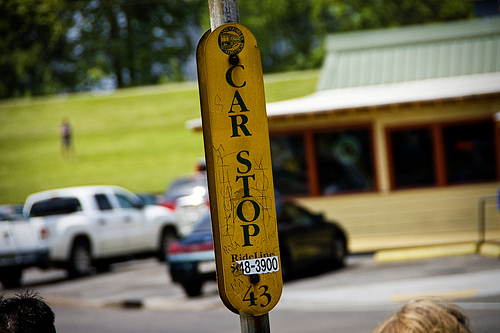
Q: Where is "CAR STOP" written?
A: On yellow sign.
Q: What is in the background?
A: Trees.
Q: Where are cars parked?
A: In a parking lot.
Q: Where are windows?
A: On a building.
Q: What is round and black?
A: Tires.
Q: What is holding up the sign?
A: A post.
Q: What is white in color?
A: Truck.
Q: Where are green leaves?
A: On trees.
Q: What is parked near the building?
A: The white truck.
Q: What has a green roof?
A: The building.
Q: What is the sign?
A: Yellow.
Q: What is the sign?
A: Yellow.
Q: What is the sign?
A: Yellow.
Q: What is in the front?
A: Sign.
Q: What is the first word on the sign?
A: Car.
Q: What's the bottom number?
A: 43.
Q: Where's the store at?
A: Far right.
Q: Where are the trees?
A: Background.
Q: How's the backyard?
A: On hill.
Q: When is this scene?
A: Afternoon.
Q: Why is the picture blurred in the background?
A: The camera was out of focus.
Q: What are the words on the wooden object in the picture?
A: "car stop.".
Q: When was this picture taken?
A: During the day.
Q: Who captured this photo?
A: A photographer.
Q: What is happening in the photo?
A: Cars are parked in front of a building.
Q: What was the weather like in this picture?
A: Sunny.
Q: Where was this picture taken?
A: On the street.